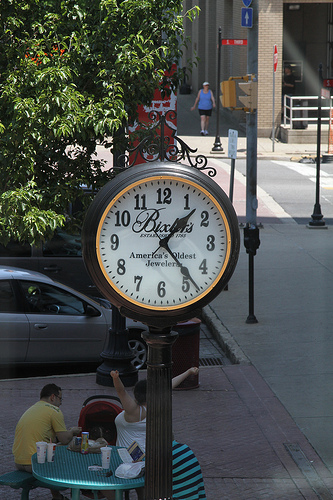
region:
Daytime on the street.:
[0, 0, 330, 498]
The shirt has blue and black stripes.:
[172, 434, 206, 497]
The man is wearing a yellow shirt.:
[7, 400, 65, 463]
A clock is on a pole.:
[79, 160, 233, 497]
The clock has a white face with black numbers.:
[93, 178, 229, 308]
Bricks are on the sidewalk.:
[181, 401, 241, 439]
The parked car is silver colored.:
[0, 263, 147, 373]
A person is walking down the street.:
[190, 78, 216, 135]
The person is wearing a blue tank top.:
[196, 88, 210, 109]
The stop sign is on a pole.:
[268, 41, 282, 154]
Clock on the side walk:
[55, 120, 251, 321]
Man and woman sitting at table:
[20, 380, 176, 485]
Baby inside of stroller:
[68, 396, 141, 466]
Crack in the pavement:
[206, 458, 303, 497]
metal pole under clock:
[141, 401, 176, 493]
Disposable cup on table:
[98, 435, 114, 463]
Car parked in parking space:
[4, 259, 151, 387]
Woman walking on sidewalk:
[184, 71, 231, 167]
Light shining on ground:
[261, 464, 320, 497]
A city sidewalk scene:
[1, 3, 328, 494]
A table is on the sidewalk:
[0, 438, 146, 498]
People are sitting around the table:
[2, 366, 207, 499]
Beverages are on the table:
[33, 430, 113, 471]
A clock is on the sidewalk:
[80, 108, 241, 498]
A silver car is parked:
[0, 266, 154, 370]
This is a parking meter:
[242, 219, 261, 323]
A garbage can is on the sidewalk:
[169, 318, 203, 391]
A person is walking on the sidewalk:
[189, 80, 217, 136]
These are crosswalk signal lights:
[217, 72, 259, 115]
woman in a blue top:
[189, 79, 217, 134]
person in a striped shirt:
[172, 438, 206, 498]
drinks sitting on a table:
[36, 438, 55, 464]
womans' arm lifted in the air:
[110, 370, 143, 419]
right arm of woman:
[173, 365, 197, 390]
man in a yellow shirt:
[11, 384, 82, 475]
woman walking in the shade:
[190, 80, 216, 136]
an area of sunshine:
[177, 136, 331, 215]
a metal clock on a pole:
[74, 109, 240, 498]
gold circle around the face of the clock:
[95, 175, 232, 310]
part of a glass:
[157, 205, 182, 236]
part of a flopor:
[229, 434, 253, 470]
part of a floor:
[238, 417, 257, 448]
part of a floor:
[243, 430, 268, 469]